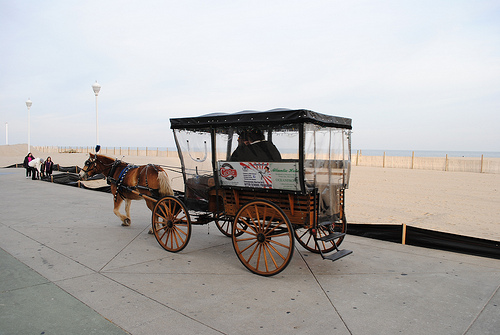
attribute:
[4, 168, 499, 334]
floor — gray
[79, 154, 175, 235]
horse — harnessed, brown, tan, discernible, on display, conspicuous, in sight, detectable, standing, walking, here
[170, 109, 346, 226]
cart — wooden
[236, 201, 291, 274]
spokes — wooden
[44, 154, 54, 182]
person — standing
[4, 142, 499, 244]
sand — brown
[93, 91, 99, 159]
pole — white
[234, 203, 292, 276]
wheel — wooden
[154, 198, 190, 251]
wheel — wooden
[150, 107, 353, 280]
wagon — painted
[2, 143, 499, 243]
beach — sandy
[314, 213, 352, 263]
steps — black, metal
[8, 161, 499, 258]
barrier — black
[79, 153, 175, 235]
visible horse — here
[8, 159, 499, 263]
fabric — black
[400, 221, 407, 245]
post — wood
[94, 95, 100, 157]
lamp post — white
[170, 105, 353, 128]
roof — black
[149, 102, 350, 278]
buggy — old fashioned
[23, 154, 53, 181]
people — standing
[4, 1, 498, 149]
sky — cloudy